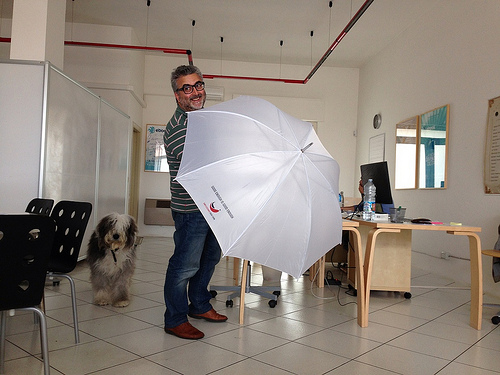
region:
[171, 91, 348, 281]
big white umbrella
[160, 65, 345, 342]
man holding an umbrella indoors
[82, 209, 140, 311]
black and white furry dog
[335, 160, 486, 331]
desk with a computer on it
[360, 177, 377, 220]
full water bottle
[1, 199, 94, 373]
three black chairs around a white table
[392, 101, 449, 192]
two frames on the wall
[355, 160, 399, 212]
Black computer monitor on the desk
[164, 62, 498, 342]
man with glasses by his desk holding an umbrella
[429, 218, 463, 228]
pink and yellow post it notes on the table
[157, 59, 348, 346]
a man with a white umbrella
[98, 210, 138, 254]
the head of a shaggy dog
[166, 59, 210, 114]
the head of a man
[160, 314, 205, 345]
a brown leather shoe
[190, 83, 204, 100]
the nose of a man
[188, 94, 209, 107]
the mouth of a man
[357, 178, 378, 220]
a water bottle on a table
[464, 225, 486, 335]
the leg of a table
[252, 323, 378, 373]
the white tile of a floor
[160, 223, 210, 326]
the leg of a man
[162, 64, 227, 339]
the man standing up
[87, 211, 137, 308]
the dog standing next to the man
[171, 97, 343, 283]
the large opened umbrella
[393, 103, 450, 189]
the framed pictures on the wall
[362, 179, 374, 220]
the water bottle on the table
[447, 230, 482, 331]
the leg under the table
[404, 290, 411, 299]
the wheel under the table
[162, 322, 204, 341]
the shoe on the man's foot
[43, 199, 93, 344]
the empty chair near the dog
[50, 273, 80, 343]
the leg on the chair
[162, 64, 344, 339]
small man and large umbrella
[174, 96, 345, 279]
white umbrella with a logo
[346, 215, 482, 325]
wooden table with curved legs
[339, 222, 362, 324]
wooden table with curved leg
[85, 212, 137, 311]
shaggy dog facing the camera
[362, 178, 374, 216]
water bottle on a wooden table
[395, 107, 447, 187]
reflection in glass on the wall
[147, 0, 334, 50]
sprinkler system outlets on ceiling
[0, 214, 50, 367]
black plastic chair on the left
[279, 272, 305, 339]
reflection on the tile floor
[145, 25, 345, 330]
man with open umbrella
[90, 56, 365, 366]
man with umbrella open inside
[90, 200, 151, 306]
dog standing beside the man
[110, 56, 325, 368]
man wearing glasses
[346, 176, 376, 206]
plastic bottle of water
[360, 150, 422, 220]
flat screen computer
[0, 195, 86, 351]
plastic chairs at a table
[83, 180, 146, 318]
fluffy white and black dog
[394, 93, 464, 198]
signs behind the desk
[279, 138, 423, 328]
wooden desk